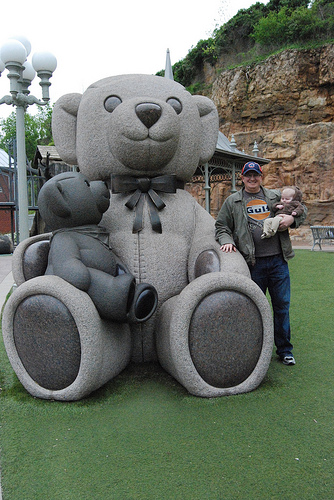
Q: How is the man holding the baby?
A: In the left arm.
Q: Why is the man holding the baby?
A: To take a picture.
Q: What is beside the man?
A: A giant teddy bear.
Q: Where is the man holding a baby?
A: An amusement park.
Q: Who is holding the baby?
A: The grandfather.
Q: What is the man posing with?
A: A huge teddy bear.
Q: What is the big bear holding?
A: A small bear.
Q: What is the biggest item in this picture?
A: A giant gray teddy bear.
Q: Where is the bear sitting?
A: The green ground.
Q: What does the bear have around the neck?
A: A bow tie.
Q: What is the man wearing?
A: A jacket.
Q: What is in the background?
A: A mountain.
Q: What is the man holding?
A: A baby.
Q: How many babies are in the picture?
A: One.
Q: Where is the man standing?
A: Beside a bear statue.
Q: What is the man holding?
A: A baby.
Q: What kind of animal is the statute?
A: Bear.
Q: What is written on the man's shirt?
A: Gulf.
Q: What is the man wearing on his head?
A: A ball cap.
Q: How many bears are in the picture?
A: Two.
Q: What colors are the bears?
A: Gray.